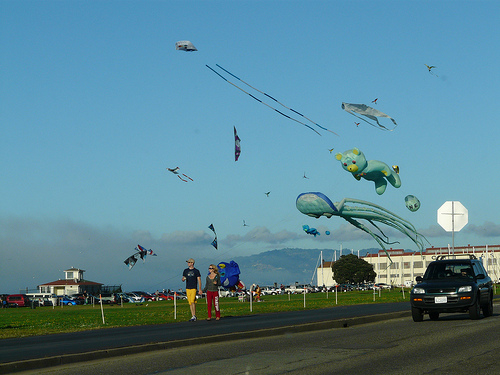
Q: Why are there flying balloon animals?
A: It's a family outing.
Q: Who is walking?
A: A man and woman.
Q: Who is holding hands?
A: The man and woman.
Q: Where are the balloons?
A: The sky.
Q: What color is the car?
A: Black.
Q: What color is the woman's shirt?
A: Green/grey.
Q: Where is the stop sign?
A: Behind the car.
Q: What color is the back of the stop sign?
A: Silver.